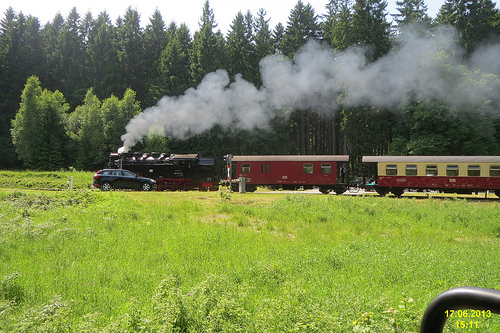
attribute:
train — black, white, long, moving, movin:
[106, 151, 500, 200]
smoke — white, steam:
[119, 16, 500, 153]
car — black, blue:
[92, 165, 158, 190]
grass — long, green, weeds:
[1, 186, 499, 330]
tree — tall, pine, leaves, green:
[187, 1, 226, 191]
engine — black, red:
[107, 152, 219, 193]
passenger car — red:
[223, 152, 352, 194]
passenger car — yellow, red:
[360, 153, 499, 197]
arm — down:
[221, 176, 239, 184]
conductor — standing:
[338, 162, 349, 184]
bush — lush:
[11, 74, 42, 171]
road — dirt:
[35, 186, 500, 204]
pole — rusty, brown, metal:
[422, 289, 498, 332]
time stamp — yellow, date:
[445, 307, 494, 329]